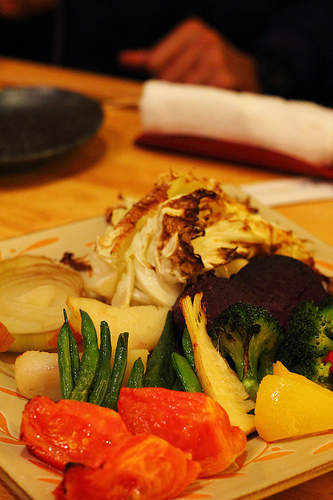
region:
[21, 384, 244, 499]
a group of three roasted red tomatoes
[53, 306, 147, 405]
six glistening green beans prepared to perfection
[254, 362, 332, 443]
one bright yellow slice of lemon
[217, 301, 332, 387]
a serving of green broccoli spears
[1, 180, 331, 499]
a square white plate with yellow decorations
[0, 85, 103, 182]
a matte black circular plate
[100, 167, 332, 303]
a wedge of roasted Chinese cabbage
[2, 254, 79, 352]
one half of a tender roasted white onion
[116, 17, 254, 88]
the fist of a white man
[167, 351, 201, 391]
a tender roasted snow pea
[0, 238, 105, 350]
roasted white onion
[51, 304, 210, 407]
roasted green beans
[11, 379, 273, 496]
three pieces of roasted red tomato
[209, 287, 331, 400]
pieces of roasted broccoli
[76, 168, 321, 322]
chunk of roasted cabbage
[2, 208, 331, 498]
plate of roasted vegetables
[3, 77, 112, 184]
black metal pan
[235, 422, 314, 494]
orange leaf pattern on the plate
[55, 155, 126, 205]
wooden table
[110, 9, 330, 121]
hand of person at the table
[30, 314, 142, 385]
fresh green beans on plate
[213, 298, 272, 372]
stalks of brocolli on plate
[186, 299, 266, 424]
pineapple on the plate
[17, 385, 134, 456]
fresh fish on plate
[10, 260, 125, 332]
onions on the plate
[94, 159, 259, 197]
yellow design on table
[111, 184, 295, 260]
fresh potatoes on plate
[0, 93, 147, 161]
pan behind the plate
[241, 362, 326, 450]
skin of yellow lemon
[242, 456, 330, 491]
outer edge of plate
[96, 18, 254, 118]
The hand is in the back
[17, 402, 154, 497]
The food is red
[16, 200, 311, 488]
The plate is square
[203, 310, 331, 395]
The broccoli is green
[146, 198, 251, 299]
The vegetable is grilled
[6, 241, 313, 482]
This is a plate of vegetables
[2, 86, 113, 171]
This is a dark colored dish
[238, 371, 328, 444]
This food is yellow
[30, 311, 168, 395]
The beans are green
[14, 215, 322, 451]
The veggies look grilled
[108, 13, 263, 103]
a hand over a table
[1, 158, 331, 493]
a dish with roasted vegetables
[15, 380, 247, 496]
three slices of tomatoes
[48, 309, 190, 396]
green bead next to tomatoes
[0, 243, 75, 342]
a half of onion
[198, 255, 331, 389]
broccoli on a dish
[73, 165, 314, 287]
leaves of cabbage in corner of dish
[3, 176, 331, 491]
a square dish with vegetables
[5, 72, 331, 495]
dish over a wooden table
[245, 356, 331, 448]
a piece of pepper